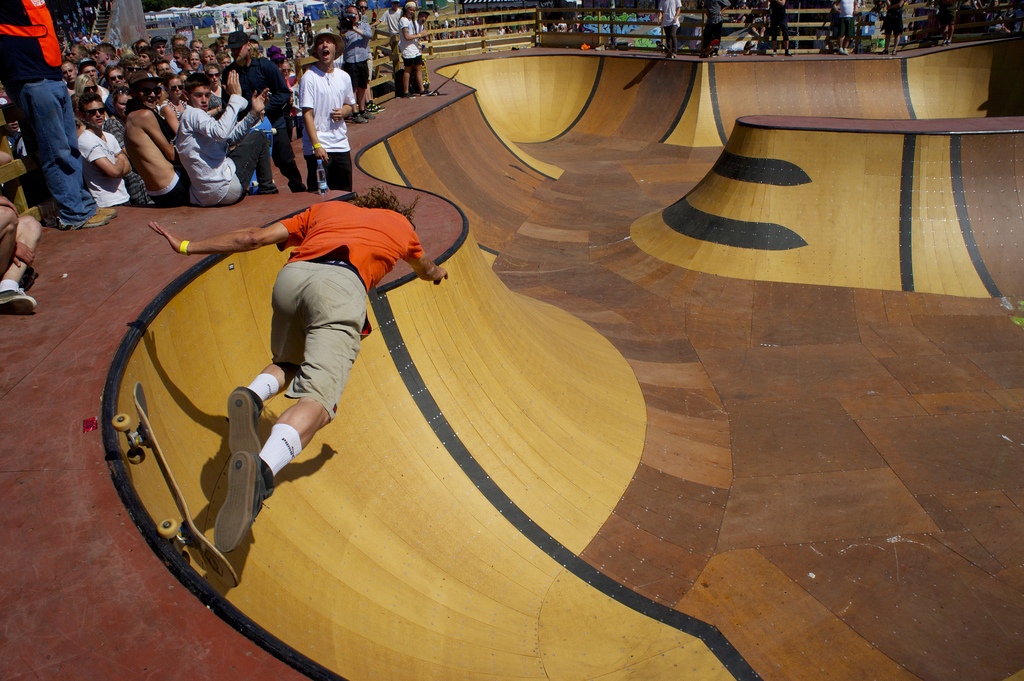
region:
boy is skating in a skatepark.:
[160, 166, 489, 629]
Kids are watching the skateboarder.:
[16, 37, 375, 178]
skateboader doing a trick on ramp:
[151, 174, 458, 605]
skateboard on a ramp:
[101, 372, 256, 600]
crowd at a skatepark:
[69, 24, 381, 215]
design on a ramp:
[633, 124, 863, 269]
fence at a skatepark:
[421, 6, 841, 62]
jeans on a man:
[11, 72, 95, 238]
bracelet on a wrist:
[173, 227, 195, 269]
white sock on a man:
[264, 413, 304, 484]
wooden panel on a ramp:
[637, 399, 747, 493]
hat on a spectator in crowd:
[301, 15, 352, 48]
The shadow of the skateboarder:
[121, 314, 336, 606]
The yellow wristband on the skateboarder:
[169, 233, 195, 257]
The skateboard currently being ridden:
[108, 374, 239, 605]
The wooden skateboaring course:
[108, 44, 1022, 680]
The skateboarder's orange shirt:
[272, 186, 421, 294]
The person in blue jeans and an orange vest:
[1, 3, 120, 232]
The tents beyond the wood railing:
[130, 3, 347, 39]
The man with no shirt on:
[115, 61, 196, 207]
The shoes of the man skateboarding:
[204, 373, 278, 560]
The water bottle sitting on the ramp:
[305, 148, 331, 202]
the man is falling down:
[153, 181, 452, 552]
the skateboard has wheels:
[111, 380, 239, 587]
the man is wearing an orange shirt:
[149, 184, 447, 549]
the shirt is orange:
[275, 199, 422, 289]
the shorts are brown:
[269, 258, 365, 423]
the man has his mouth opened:
[298, 23, 356, 192]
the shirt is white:
[296, 66, 358, 155]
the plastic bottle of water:
[314, 157, 328, 196]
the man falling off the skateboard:
[138, 186, 455, 557]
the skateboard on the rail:
[130, 380, 238, 590]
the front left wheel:
[113, 407, 134, 433]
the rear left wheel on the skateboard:
[158, 513, 181, 537]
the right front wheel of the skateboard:
[128, 443, 148, 466]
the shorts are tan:
[268, 257, 371, 422]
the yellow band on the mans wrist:
[174, 237, 190, 257]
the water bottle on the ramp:
[313, 155, 333, 197]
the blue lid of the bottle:
[315, 155, 325, 165]